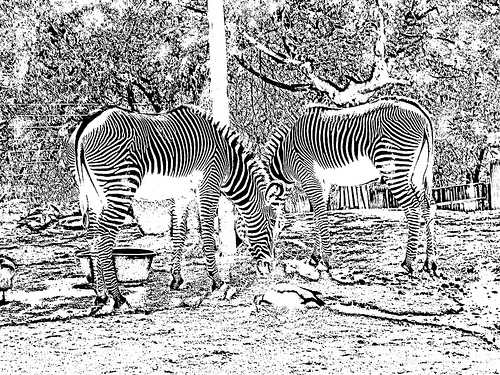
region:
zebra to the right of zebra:
[258, 96, 441, 285]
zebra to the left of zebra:
[66, 101, 291, 313]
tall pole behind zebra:
[203, 1, 228, 124]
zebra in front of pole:
[66, 102, 283, 316]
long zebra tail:
[423, 123, 438, 217]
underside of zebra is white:
[309, 159, 379, 186]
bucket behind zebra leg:
[76, 247, 156, 308]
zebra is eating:
[66, 100, 286, 318]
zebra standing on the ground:
[260, 95, 442, 277]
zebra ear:
[263, 180, 284, 202]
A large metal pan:
[73, 240, 156, 282]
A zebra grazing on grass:
[74, 105, 276, 302]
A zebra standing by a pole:
[276, 102, 450, 269]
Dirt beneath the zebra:
[113, 312, 253, 361]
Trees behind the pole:
[268, 4, 443, 82]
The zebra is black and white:
[261, 102, 439, 256]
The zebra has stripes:
[73, 111, 279, 284]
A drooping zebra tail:
[63, 130, 118, 229]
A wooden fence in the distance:
[436, 182, 487, 223]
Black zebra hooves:
[92, 287, 132, 312]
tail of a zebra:
[404, 127, 453, 185]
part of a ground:
[297, 334, 323, 359]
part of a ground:
[188, 297, 233, 339]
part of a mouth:
[257, 266, 276, 298]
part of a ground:
[222, 300, 263, 353]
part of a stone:
[273, 289, 305, 331]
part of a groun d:
[200, 297, 224, 322]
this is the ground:
[200, 323, 277, 368]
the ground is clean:
[193, 320, 248, 355]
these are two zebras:
[58, 95, 442, 310]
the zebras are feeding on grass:
[228, 156, 304, 275]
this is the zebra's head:
[240, 182, 291, 279]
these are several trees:
[2, 7, 492, 94]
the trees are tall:
[291, 12, 485, 96]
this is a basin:
[118, 250, 155, 282]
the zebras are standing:
[67, 112, 449, 321]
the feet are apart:
[168, 207, 236, 295]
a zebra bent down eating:
[65, 87, 307, 347]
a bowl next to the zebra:
[56, 227, 171, 298]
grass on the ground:
[196, 307, 319, 370]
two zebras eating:
[32, 55, 493, 355]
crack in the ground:
[332, 281, 439, 361]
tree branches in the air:
[284, 41, 407, 99]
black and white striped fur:
[123, 107, 201, 177]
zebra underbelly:
[308, 133, 411, 202]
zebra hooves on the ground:
[300, 248, 455, 294]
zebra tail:
[68, 119, 121, 251]